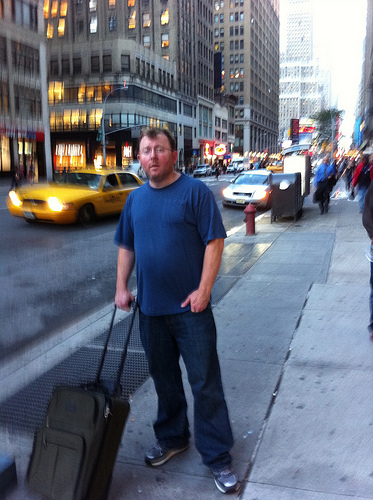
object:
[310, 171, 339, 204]
jacket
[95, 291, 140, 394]
handle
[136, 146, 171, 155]
glasses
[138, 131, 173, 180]
face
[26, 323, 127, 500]
suitcase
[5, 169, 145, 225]
taxi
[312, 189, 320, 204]
briefcase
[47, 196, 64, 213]
light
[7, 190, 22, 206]
light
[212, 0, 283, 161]
building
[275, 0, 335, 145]
building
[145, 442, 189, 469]
sneaker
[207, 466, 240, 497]
sneaker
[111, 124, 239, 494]
man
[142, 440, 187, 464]
foot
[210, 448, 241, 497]
foot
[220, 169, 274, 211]
car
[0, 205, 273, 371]
curb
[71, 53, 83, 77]
window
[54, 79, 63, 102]
window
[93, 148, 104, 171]
window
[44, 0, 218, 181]
building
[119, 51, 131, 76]
window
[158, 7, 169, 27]
window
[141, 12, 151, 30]
window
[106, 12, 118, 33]
window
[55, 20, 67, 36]
window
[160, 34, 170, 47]
window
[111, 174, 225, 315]
shirt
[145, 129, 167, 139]
peak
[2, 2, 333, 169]
row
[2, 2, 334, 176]
skyscrapers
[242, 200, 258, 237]
hydrant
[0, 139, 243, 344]
street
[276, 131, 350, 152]
streetlight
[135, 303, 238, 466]
jeans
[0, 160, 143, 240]
cab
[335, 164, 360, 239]
man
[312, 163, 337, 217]
suit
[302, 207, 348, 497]
sidewalk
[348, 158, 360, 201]
person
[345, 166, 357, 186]
jacket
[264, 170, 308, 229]
mail box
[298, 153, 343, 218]
man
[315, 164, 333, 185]
shirt